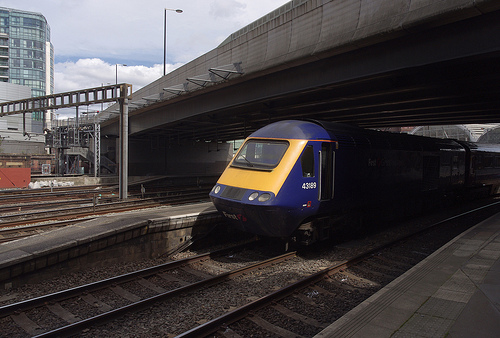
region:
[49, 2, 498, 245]
train is sticking out under the bridge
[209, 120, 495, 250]
two-toned train has numbers under the window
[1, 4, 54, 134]
tall building seen in the background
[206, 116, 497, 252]
train has four head lights under the windshield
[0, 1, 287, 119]
white clouds fills the sky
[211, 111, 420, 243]
blue and yellow train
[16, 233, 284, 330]
train on brown tracks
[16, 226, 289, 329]
wood in between tracks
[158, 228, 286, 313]
grey ballast between tracks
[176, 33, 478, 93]
bridge is over train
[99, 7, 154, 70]
thick clouds in sky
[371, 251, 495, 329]
grey and concrete platform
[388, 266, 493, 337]
platform next to tracks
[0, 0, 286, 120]
white clouds in sky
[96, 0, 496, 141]
underside of concrete bridge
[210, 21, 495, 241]
commuter train under bridge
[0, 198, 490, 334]
two sets of train tracks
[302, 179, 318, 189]
white numbers on blue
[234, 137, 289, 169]
windshield on commuter train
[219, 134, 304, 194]
yellow front of train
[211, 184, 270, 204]
four lights of train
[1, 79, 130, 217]
metal frame above tracks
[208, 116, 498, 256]
train travelling under a bridge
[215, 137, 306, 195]
front of train is yellow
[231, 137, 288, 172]
train has a windshield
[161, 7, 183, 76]
street light above bridge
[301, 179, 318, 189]
number printed on train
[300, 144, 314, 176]
side window above number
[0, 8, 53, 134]
tall glass building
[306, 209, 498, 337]
gray platform to the right of the train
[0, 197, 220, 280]
narrow cement walkway to the left train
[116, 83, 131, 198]
metal post supporting a beam across the tracks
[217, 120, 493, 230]
blue and yellow train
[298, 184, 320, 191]
white numbers on blue background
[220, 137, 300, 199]
yellow front of the train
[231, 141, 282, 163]
windshield of the first train car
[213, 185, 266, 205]
headlights on the train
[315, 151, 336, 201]
door to the first train car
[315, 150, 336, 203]
silver handle bars beside the door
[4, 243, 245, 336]
tracks the train is on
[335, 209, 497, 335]
platform next to train tracks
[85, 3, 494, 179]
bridge above the train tracks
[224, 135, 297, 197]
train's front is yellow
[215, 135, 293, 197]
train's front is yellow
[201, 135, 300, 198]
train's front is yellow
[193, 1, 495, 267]
a train under a bridge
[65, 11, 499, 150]
bridge above the train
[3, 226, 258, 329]
tracks in front of the train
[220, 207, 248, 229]
part of train that says fedex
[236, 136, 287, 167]
front windshield of the train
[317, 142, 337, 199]
side door of the train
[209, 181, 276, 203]
front lights of the train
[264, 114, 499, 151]
top of the train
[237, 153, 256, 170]
windshield wiper of the train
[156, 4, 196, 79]
street light up on bridge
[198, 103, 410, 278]
The train is yellow and blue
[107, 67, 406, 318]
The train is on the tracks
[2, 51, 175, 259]
A metal post is over the tracks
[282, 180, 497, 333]
The platform is next to the tracks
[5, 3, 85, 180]
The building is blue